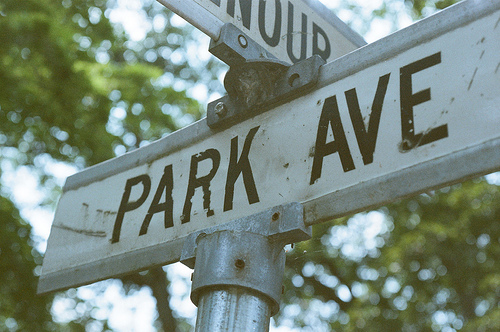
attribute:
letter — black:
[138, 159, 177, 239]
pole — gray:
[198, 288, 272, 330]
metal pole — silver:
[188, 283, 276, 330]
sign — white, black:
[32, 0, 499, 302]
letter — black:
[308, 68, 353, 195]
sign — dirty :
[124, 2, 456, 255]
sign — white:
[32, 22, 490, 233]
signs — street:
[37, 93, 454, 258]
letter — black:
[394, 50, 449, 150]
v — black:
[336, 69, 389, 166]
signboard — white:
[42, 38, 479, 298]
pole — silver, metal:
[195, 230, 307, 329]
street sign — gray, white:
[34, 2, 499, 299]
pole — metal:
[169, 204, 339, 314]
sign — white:
[26, 37, 446, 291]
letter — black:
[220, 119, 262, 213]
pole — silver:
[109, 179, 350, 325]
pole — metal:
[179, 233, 275, 330]